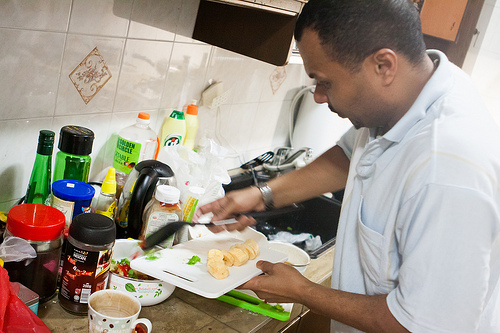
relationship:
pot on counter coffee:
[107, 149, 183, 240] [63, 204, 113, 313]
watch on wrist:
[252, 178, 279, 208] [239, 168, 295, 219]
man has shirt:
[191, 2, 497, 331] [326, 46, 499, 332]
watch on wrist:
[256, 181, 276, 210] [249, 174, 286, 213]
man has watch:
[191, 2, 497, 331] [256, 181, 276, 210]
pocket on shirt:
[357, 197, 390, 280] [319, 102, 499, 332]